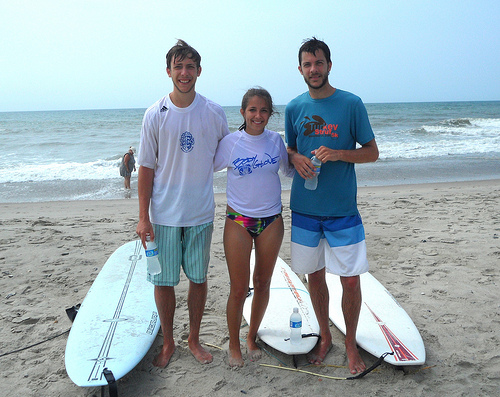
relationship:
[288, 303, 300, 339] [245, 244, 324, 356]
bottle on surfboard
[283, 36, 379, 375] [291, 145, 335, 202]
man holding bottle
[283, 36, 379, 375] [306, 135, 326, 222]
man holding bottle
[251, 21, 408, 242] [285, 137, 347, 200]
man holding bottle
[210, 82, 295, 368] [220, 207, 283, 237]
woman wearing bottom